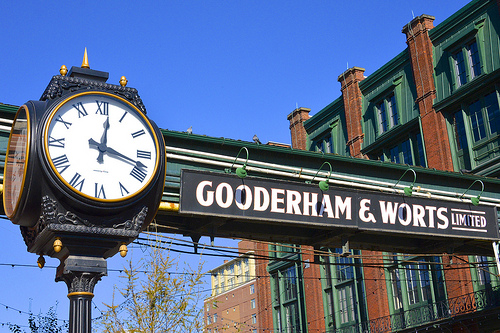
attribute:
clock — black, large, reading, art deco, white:
[43, 91, 163, 210]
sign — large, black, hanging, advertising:
[181, 168, 500, 241]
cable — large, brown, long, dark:
[145, 221, 493, 263]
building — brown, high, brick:
[205, 239, 275, 332]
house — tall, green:
[258, 3, 498, 332]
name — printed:
[197, 181, 490, 232]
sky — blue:
[0, 1, 473, 333]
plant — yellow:
[99, 221, 253, 331]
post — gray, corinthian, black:
[59, 253, 109, 332]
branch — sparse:
[11, 306, 65, 331]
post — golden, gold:
[80, 48, 91, 69]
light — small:
[229, 145, 250, 179]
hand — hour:
[98, 117, 112, 162]